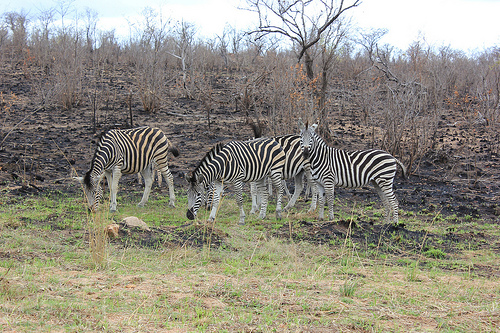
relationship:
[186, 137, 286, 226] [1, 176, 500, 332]
zebra in middle of field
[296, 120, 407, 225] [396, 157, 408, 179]
zebra has tail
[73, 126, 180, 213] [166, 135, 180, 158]
zebra has tail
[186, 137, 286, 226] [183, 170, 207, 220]
zebra has head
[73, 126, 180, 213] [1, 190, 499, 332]
zebra eating grass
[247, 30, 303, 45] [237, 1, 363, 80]
branch of tree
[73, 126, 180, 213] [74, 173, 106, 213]
zebra has head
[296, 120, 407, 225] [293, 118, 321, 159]
zebra has head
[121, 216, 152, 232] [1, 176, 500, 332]
rock in middle of field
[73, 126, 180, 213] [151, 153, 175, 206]
zebra has leg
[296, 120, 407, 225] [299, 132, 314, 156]
zebra has face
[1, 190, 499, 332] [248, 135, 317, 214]
grass in front of zebra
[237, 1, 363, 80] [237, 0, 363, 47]
tree has top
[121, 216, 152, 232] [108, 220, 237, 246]
rock on top of dirt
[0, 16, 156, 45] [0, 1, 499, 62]
cloud in middle of sky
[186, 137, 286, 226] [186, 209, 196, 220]
zebra has nose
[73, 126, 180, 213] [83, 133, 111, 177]
zebra has neck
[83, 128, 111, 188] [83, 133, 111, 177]
mane on top of neck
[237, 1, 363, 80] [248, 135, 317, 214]
tree behind zebra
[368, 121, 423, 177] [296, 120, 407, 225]
brush behind zebra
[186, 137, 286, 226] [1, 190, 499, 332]
zebra grazing from grass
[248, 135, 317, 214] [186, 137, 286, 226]
zebra obscured by zebra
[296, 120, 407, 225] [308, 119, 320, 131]
zebra has ear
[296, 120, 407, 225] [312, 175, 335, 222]
zebra has leg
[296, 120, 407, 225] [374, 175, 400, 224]
zebra has leg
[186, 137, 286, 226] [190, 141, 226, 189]
zebra has mane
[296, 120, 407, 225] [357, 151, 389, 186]
zebra has stripe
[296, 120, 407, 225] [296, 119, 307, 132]
zebra has ear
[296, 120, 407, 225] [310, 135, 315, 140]
zebra has eye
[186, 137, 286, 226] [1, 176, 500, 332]
zebra standing in field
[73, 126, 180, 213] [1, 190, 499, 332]
zebra on top of grass